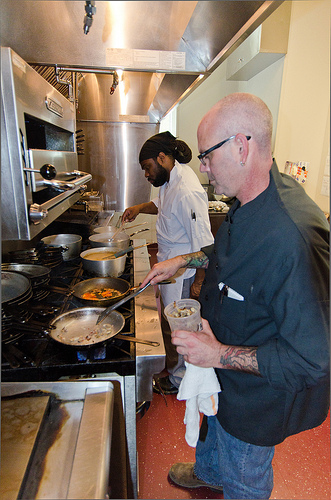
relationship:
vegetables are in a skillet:
[81, 285, 122, 299] [68, 279, 150, 304]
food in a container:
[171, 300, 198, 323] [163, 300, 204, 341]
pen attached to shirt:
[215, 282, 229, 316] [195, 159, 329, 450]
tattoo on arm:
[178, 252, 210, 271] [144, 242, 221, 283]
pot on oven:
[78, 244, 147, 274] [2, 243, 163, 500]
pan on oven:
[42, 309, 161, 354] [2, 243, 163, 500]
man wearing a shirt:
[123, 128, 211, 400] [149, 162, 210, 275]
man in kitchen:
[111, 89, 329, 499] [2, 0, 330, 499]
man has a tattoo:
[111, 89, 329, 499] [178, 252, 210, 271]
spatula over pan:
[89, 280, 156, 329] [42, 309, 161, 354]